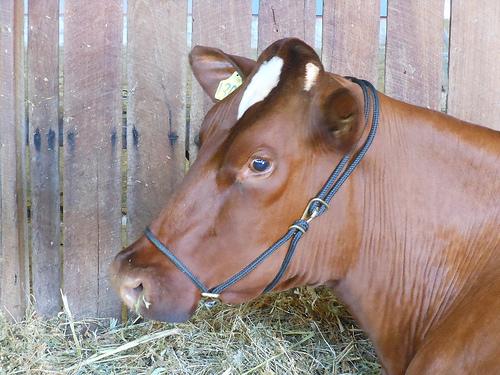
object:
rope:
[143, 75, 380, 299]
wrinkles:
[359, 145, 493, 346]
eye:
[252, 159, 269, 172]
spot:
[304, 62, 318, 91]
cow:
[109, 38, 500, 375]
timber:
[61, 0, 124, 317]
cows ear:
[188, 45, 257, 103]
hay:
[0, 286, 385, 375]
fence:
[0, 0, 500, 324]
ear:
[323, 87, 363, 154]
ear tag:
[214, 71, 244, 101]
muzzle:
[108, 248, 199, 324]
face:
[124, 101, 278, 295]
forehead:
[245, 37, 323, 101]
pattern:
[237, 57, 284, 120]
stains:
[34, 126, 179, 151]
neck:
[342, 82, 500, 375]